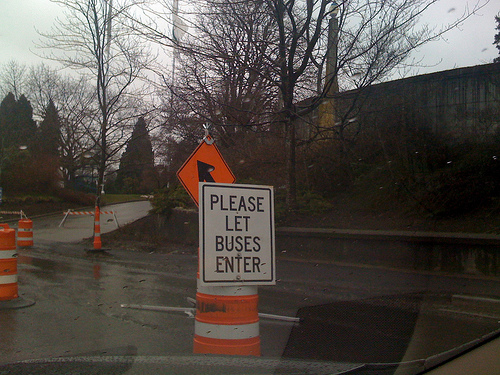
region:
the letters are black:
[175, 157, 290, 297]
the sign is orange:
[166, 118, 249, 193]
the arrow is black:
[185, 143, 229, 189]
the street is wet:
[44, 241, 159, 341]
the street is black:
[56, 257, 171, 322]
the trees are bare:
[200, 0, 367, 217]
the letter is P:
[204, 185, 224, 215]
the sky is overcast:
[0, 5, 165, 108]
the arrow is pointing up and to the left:
[173, 148, 231, 189]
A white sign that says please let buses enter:
[199, 180, 276, 285]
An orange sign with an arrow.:
[175, 132, 236, 214]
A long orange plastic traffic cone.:
[90, 203, 107, 254]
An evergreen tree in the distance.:
[113, 113, 158, 195]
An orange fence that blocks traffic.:
[57, 207, 120, 231]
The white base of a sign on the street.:
[117, 293, 302, 328]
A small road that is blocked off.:
[0, 197, 160, 242]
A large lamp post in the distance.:
[320, 0, 347, 145]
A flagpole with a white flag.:
[165, 3, 188, 205]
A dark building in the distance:
[270, 62, 498, 170]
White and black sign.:
[198, 182, 275, 285]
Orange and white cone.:
[192, 245, 260, 354]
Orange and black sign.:
[178, 130, 235, 207]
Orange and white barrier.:
[57, 205, 94, 229]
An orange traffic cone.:
[15, 214, 34, 248]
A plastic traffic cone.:
[1, 220, 18, 300]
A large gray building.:
[278, 61, 499, 147]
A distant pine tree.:
[115, 110, 158, 191]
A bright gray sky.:
[0, 0, 284, 171]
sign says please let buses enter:
[156, 102, 311, 317]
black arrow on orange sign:
[168, 120, 253, 225]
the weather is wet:
[16, 60, 288, 372]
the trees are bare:
[68, 13, 357, 135]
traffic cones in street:
[16, 159, 308, 368]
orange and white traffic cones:
[10, 176, 138, 298]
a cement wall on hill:
[241, 54, 498, 261]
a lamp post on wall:
[317, 7, 364, 113]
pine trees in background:
[8, 82, 170, 194]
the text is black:
[168, 105, 314, 330]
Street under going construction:
[5, 43, 490, 370]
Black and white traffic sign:
[193, 179, 281, 288]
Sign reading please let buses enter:
[197, 178, 277, 288]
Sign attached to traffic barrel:
[191, 180, 278, 357]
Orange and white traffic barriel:
[189, 238, 261, 356]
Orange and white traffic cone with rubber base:
[86, 205, 109, 257]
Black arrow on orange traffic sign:
[175, 118, 238, 204]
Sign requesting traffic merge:
[174, 128, 239, 210]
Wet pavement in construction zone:
[1, 235, 499, 366]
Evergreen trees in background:
[0, 90, 161, 204]